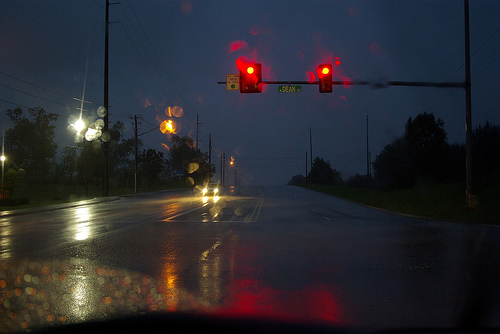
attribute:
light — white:
[61, 194, 109, 248]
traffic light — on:
[316, 53, 334, 93]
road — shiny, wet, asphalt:
[2, 183, 488, 332]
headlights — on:
[200, 185, 220, 195]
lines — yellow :
[226, 182, 266, 223]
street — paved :
[133, 204, 318, 269]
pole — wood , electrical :
[304, 126, 314, 184]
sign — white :
[221, 71, 241, 92]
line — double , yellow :
[239, 193, 269, 225]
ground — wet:
[0, 182, 487, 324]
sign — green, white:
[275, 84, 305, 94]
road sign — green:
[276, 85, 303, 95]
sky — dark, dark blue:
[2, 3, 483, 185]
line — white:
[322, 216, 331, 222]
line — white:
[308, 208, 318, 215]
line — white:
[301, 199, 309, 207]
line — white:
[299, 196, 304, 200]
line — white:
[288, 191, 291, 194]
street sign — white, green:
[275, 82, 304, 94]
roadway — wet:
[2, 181, 484, 330]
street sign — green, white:
[276, 81, 302, 93]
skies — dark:
[97, 20, 257, 107]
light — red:
[233, 58, 260, 84]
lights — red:
[230, 51, 366, 94]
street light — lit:
[60, 103, 116, 160]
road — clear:
[235, 191, 415, 331]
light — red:
[217, 51, 360, 97]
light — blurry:
[233, 50, 335, 81]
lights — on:
[196, 184, 235, 204]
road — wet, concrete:
[0, 183, 443, 313]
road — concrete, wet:
[0, 183, 416, 321]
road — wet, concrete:
[0, 181, 392, 302]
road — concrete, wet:
[4, 181, 399, 312]